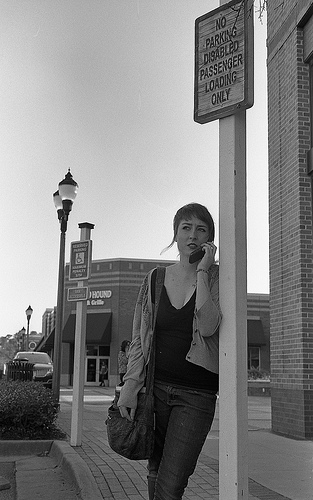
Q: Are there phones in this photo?
A: Yes, there is a phone.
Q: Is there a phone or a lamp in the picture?
A: Yes, there is a phone.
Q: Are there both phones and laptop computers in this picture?
A: No, there is a phone but no laptops.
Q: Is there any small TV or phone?
A: Yes, there is a small phone.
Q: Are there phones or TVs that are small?
A: Yes, the phone is small.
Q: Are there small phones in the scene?
A: Yes, there is a small phone.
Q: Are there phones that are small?
A: Yes, there is a phone that is small.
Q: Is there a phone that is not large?
A: Yes, there is a small phone.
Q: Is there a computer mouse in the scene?
A: No, there are no computer mice.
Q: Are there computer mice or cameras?
A: No, there are no computer mice or cameras.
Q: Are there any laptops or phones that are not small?
A: No, there is a phone but it is small.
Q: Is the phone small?
A: Yes, the phone is small.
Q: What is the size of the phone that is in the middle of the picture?
A: The telephone is small.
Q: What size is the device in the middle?
A: The telephone is small.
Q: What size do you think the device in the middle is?
A: The telephone is small.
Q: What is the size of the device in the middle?
A: The telephone is small.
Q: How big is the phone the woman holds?
A: The telephone is small.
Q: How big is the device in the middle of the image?
A: The telephone is small.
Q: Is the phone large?
A: No, the phone is small.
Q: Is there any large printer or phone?
A: No, there is a phone but it is small.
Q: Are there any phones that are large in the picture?
A: No, there is a phone but it is small.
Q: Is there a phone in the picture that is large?
A: No, there is a phone but it is small.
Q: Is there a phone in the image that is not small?
A: No, there is a phone but it is small.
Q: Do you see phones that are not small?
A: No, there is a phone but it is small.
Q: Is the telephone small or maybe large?
A: The telephone is small.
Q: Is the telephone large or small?
A: The telephone is small.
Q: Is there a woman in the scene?
A: Yes, there is a woman.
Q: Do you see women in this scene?
A: Yes, there is a woman.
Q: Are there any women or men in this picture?
A: Yes, there is a woman.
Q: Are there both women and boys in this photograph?
A: No, there is a woman but no boys.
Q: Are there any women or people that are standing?
A: Yes, the woman is standing.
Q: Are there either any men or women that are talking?
A: Yes, the woman is talking.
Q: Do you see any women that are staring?
A: Yes, there is a woman that is staring.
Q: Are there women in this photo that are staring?
A: Yes, there is a woman that is staring.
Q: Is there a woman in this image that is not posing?
A: Yes, there is a woman that is staring.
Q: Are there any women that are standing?
A: Yes, there is a woman that is standing.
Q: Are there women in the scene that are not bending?
A: Yes, there is a woman that is standing.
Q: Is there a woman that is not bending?
A: Yes, there is a woman that is standing.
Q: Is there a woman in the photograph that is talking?
A: Yes, there is a woman that is talking.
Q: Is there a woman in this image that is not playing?
A: Yes, there is a woman that is talking.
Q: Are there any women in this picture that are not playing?
A: Yes, there is a woman that is talking.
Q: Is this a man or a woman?
A: This is a woman.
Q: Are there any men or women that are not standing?
A: No, there is a woman but she is standing.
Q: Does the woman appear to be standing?
A: Yes, the woman is standing.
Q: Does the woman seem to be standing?
A: Yes, the woman is standing.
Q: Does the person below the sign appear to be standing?
A: Yes, the woman is standing.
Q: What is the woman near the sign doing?
A: The woman is standing.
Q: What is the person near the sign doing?
A: The woman is standing.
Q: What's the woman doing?
A: The woman is standing.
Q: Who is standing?
A: The woman is standing.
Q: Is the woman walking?
A: No, the woman is standing.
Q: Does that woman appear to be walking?
A: No, the woman is standing.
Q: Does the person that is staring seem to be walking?
A: No, the woman is standing.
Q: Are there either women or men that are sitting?
A: No, there is a woman but she is standing.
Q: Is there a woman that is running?
A: No, there is a woman but she is standing.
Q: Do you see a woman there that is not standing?
A: No, there is a woman but she is standing.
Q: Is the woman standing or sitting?
A: The woman is standing.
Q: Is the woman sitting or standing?
A: The woman is standing.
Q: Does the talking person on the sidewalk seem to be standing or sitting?
A: The woman is standing.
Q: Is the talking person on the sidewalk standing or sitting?
A: The woman is standing.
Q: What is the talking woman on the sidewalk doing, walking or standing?
A: The woman is standing.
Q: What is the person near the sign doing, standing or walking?
A: The woman is standing.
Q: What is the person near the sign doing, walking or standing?
A: The woman is standing.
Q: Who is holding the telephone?
A: The woman is holding the telephone.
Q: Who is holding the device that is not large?
A: The woman is holding the telephone.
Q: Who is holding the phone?
A: The woman is holding the telephone.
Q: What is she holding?
A: The woman is holding the telephone.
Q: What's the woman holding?
A: The woman is holding the telephone.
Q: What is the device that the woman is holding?
A: The device is a phone.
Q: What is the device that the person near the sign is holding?
A: The device is a phone.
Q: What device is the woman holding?
A: The woman is holding the telephone.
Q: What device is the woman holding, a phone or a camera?
A: The woman is holding a phone.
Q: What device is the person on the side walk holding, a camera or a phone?
A: The woman is holding a phone.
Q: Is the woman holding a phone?
A: Yes, the woman is holding a phone.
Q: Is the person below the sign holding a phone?
A: Yes, the woman is holding a phone.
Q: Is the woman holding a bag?
A: No, the woman is holding a phone.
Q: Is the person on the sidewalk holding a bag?
A: No, the woman is holding a phone.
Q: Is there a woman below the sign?
A: Yes, there is a woman below the sign.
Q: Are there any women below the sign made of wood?
A: Yes, there is a woman below the sign.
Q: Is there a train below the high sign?
A: No, there is a woman below the sign.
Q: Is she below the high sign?
A: Yes, the woman is below the sign.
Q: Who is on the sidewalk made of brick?
A: The woman is on the sidewalk.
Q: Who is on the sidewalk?
A: The woman is on the sidewalk.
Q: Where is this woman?
A: The woman is on the sidewalk.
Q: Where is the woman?
A: The woman is on the sidewalk.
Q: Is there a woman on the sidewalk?
A: Yes, there is a woman on the sidewalk.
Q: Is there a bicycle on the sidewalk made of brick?
A: No, there is a woman on the side walk.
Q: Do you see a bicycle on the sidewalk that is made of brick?
A: No, there is a woman on the side walk.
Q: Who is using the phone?
A: The woman is using the phone.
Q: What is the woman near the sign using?
A: The woman is using a phone.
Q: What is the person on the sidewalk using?
A: The woman is using a phone.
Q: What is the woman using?
A: The woman is using a phone.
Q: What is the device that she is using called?
A: The device is a phone.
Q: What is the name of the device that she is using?
A: The device is a phone.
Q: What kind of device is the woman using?
A: The woman is using a phone.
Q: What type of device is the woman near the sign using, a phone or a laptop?
A: The woman is using a phone.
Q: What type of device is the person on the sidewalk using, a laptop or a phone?
A: The woman is using a phone.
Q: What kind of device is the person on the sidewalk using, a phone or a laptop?
A: The woman is using a phone.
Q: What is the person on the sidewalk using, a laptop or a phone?
A: The woman is using a phone.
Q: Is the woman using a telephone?
A: Yes, the woman is using a telephone.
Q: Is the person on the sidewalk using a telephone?
A: Yes, the woman is using a telephone.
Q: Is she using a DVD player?
A: No, the woman is using a telephone.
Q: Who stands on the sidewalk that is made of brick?
A: The woman stands on the sidewalk.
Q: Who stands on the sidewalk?
A: The woman stands on the sidewalk.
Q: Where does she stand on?
A: The woman stands on the side walk.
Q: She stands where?
A: The woman stands on the side walk.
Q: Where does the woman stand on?
A: The woman stands on the side walk.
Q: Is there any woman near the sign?
A: Yes, there is a woman near the sign.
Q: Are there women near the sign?
A: Yes, there is a woman near the sign.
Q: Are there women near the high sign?
A: Yes, there is a woman near the sign.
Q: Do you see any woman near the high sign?
A: Yes, there is a woman near the sign.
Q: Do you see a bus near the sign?
A: No, there is a woman near the sign.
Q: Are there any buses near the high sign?
A: No, there is a woman near the sign.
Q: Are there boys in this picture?
A: No, there are no boys.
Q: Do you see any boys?
A: No, there are no boys.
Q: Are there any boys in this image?
A: No, there are no boys.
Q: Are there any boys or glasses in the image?
A: No, there are no boys or glasses.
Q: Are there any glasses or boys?
A: No, there are no boys or glasses.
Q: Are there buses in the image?
A: No, there are no buses.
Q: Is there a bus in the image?
A: No, there are no buses.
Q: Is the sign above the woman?
A: Yes, the sign is above the woman.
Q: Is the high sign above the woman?
A: Yes, the sign is above the woman.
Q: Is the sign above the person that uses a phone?
A: Yes, the sign is above the woman.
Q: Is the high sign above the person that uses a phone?
A: Yes, the sign is above the woman.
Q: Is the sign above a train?
A: No, the sign is above the woman.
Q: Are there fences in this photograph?
A: No, there are no fences.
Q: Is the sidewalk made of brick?
A: Yes, the sidewalk is made of brick.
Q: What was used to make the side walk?
A: The side walk is made of brick.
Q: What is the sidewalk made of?
A: The side walk is made of brick.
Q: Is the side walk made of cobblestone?
A: No, the side walk is made of brick.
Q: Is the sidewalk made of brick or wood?
A: The sidewalk is made of brick.